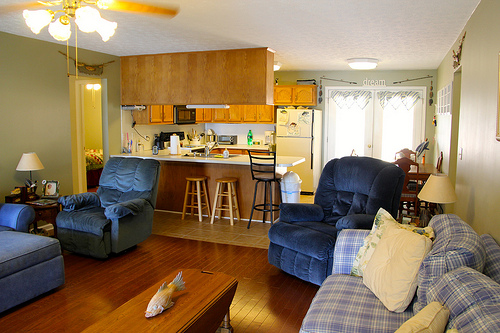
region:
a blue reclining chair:
[45, 147, 171, 287]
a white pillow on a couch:
[353, 219, 445, 326]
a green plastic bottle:
[245, 122, 257, 154]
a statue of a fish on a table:
[111, 267, 196, 332]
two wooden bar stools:
[170, 174, 243, 224]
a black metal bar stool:
[248, 140, 287, 231]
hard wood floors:
[87, 231, 173, 308]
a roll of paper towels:
[165, 123, 183, 170]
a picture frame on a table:
[35, 170, 59, 217]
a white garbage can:
[268, 155, 310, 217]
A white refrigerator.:
[276, 107, 316, 194]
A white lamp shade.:
[418, 169, 458, 204]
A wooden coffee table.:
[72, 260, 244, 331]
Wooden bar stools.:
[176, 171, 241, 226]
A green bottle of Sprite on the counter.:
[244, 128, 256, 145]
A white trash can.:
[279, 168, 301, 213]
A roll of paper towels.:
[166, 133, 183, 155]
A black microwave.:
[174, 106, 196, 125]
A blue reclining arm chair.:
[56, 150, 161, 263]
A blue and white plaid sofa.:
[294, 217, 498, 331]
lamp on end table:
[13, 145, 50, 204]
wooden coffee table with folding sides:
[88, 261, 245, 331]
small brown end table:
[24, 194, 66, 234]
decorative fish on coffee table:
[134, 268, 193, 323]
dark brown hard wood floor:
[81, 265, 131, 302]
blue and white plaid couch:
[302, 222, 499, 331]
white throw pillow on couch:
[357, 220, 430, 317]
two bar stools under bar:
[176, 171, 246, 234]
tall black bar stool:
[237, 148, 289, 242]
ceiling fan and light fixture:
[8, 3, 178, 46]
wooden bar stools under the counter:
[181, 173, 241, 227]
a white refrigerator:
[273, 106, 321, 193]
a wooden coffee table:
[79, 267, 239, 331]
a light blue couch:
[299, 211, 499, 331]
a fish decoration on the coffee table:
[143, 268, 187, 316]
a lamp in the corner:
[15, 150, 42, 190]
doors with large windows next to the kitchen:
[323, 85, 427, 181]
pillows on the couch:
[351, 205, 452, 331]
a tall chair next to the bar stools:
[248, 147, 283, 228]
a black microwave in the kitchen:
[173, 106, 196, 123]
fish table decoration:
[141, 262, 191, 329]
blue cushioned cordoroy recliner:
[250, 142, 410, 297]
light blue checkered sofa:
[295, 197, 496, 328]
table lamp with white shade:
[5, 150, 52, 200]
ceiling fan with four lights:
[1, 1, 179, 84]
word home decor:
[358, 73, 389, 92]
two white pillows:
[346, 207, 434, 306]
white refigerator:
[271, 102, 328, 207]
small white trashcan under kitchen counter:
[282, 170, 305, 218]